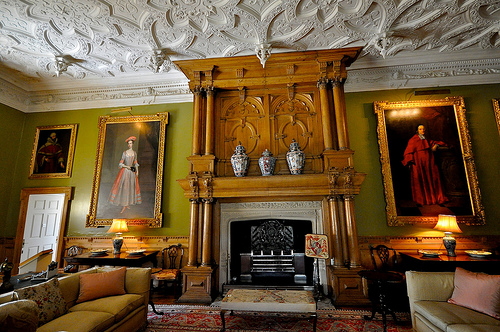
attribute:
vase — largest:
[287, 138, 305, 176]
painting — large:
[86, 109, 170, 230]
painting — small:
[27, 120, 79, 178]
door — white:
[20, 191, 65, 266]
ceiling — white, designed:
[2, 0, 499, 86]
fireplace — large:
[219, 202, 318, 291]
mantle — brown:
[177, 173, 367, 196]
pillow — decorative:
[77, 266, 128, 302]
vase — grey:
[259, 147, 276, 178]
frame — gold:
[154, 113, 169, 229]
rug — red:
[136, 303, 415, 331]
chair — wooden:
[150, 245, 186, 300]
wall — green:
[341, 91, 386, 236]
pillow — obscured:
[0, 301, 42, 331]